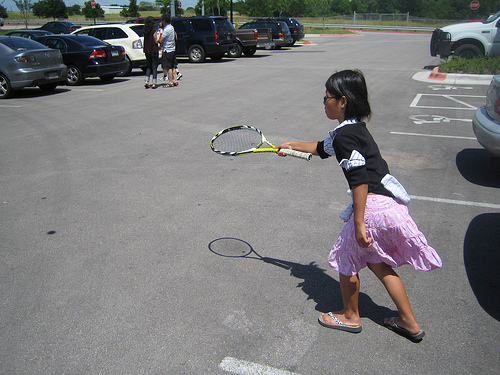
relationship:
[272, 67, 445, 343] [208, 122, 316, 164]
girl playing with tennis racket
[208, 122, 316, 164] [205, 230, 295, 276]
tennis racket has shadow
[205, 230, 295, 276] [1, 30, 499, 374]
shadow on pavement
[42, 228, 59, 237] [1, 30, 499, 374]
shadow on pavement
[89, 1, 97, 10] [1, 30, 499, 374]
stop sign near pavement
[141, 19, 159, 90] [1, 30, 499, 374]
person standing on pavement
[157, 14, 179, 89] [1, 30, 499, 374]
person standing on pavement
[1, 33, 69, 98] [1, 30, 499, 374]
car parked on pavement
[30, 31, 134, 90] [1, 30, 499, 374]
car parked on pavement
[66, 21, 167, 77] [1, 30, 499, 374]
car parked on pavement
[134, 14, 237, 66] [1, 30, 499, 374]
car parked on pavement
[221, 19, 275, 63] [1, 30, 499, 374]
car parked on pavement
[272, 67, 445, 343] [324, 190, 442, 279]
girl wearing skirt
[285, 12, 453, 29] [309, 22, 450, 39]
fence across street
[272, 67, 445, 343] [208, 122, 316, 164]
girl holding tennis racket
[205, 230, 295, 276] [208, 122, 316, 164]
shadow of tennis racket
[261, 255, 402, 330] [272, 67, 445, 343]
shadow of girl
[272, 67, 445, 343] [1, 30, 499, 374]
girl on pavement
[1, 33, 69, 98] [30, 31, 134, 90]
car next to car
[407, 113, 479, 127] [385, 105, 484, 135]
handicapped sign in parking space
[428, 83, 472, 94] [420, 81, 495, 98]
handicapped sign in parking space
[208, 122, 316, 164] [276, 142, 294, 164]
tennis racket in hand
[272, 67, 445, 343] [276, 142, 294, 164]
girl has hand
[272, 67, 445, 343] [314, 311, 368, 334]
girl has flip flop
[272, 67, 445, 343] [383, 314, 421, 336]
girl has right foot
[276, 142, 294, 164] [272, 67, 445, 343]
hand of girl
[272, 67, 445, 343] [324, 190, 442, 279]
girl has skirt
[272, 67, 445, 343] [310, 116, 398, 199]
girl has shirt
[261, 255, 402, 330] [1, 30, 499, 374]
shadow on pavement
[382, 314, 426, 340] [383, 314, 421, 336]
flip flop on right foot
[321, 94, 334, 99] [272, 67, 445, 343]
glasses are on girl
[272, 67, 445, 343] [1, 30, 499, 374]
girl standing on pavement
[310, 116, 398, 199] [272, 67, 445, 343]
shirt on girl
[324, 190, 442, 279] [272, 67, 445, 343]
skirt on girl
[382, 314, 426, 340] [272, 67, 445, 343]
flip flop on girl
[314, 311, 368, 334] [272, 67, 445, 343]
flip flop on girl